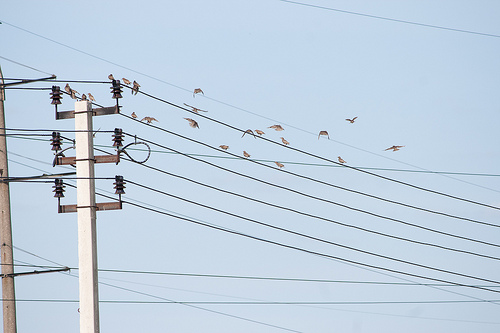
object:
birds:
[346, 116, 359, 123]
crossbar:
[49, 127, 126, 166]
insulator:
[113, 175, 127, 194]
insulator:
[111, 128, 124, 147]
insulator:
[109, 78, 123, 98]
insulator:
[51, 178, 67, 197]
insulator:
[51, 132, 64, 150]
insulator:
[49, 85, 63, 104]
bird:
[384, 145, 406, 152]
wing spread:
[382, 144, 406, 152]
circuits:
[46, 83, 76, 214]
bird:
[281, 136, 290, 146]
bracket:
[92, 127, 124, 165]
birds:
[338, 155, 349, 165]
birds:
[243, 150, 252, 159]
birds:
[130, 111, 137, 119]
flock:
[63, 72, 407, 169]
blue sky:
[15, 5, 500, 158]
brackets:
[90, 79, 121, 116]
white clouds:
[399, 98, 495, 155]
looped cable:
[122, 141, 151, 163]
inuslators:
[112, 126, 125, 149]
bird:
[317, 130, 330, 140]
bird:
[219, 144, 229, 150]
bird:
[182, 116, 201, 130]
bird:
[140, 116, 159, 124]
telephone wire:
[157, 150, 414, 250]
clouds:
[55, 0, 500, 278]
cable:
[0, 22, 500, 306]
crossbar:
[48, 83, 124, 121]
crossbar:
[52, 174, 127, 213]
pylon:
[67, 97, 101, 330]